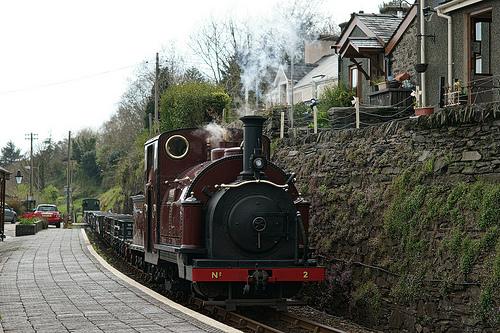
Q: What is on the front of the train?
A: An engine.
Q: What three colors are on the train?
A: Burgundy, black and red.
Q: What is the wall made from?
A: Stone.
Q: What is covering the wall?
A: Vegetation.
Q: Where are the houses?
A: Behind the stone wall.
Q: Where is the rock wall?
A: Next to the train.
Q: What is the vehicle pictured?
A: Train.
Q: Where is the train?
A: On tracks.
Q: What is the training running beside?
A: Homes.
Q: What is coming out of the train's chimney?
A: Steam.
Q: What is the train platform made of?
A: Paving stones.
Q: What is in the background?
A: Trees.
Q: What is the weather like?
A: Rainy.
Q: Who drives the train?
A: Conductor.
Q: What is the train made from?
A: Metal.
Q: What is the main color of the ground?
A: Grey.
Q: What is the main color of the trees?
A: Green.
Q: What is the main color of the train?
A: Red and black.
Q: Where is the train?
A: On the track.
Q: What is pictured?
A: A train.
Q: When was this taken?
A: During the day.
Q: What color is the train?
A: Brown.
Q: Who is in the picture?
A: No one.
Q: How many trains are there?
A: One.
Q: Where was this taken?
A: Outside on a train track.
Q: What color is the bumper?
A: Red.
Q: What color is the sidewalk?
A: Gray.